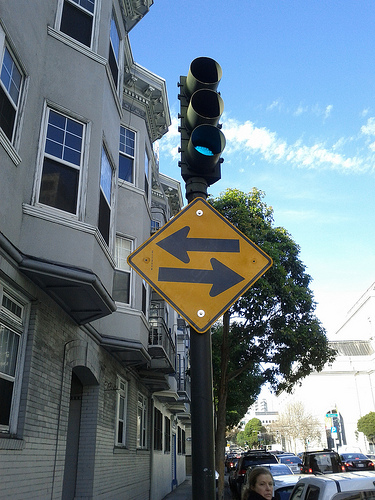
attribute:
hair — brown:
[242, 469, 272, 500]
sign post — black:
[177, 55, 224, 499]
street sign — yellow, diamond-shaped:
[126, 196, 272, 335]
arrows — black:
[156, 224, 245, 298]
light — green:
[186, 125, 226, 170]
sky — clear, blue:
[132, 0, 370, 337]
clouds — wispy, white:
[153, 98, 374, 169]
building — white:
[0, 0, 191, 498]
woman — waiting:
[237, 466, 275, 500]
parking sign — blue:
[329, 423, 339, 432]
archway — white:
[52, 341, 103, 499]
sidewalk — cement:
[158, 471, 229, 499]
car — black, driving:
[338, 453, 374, 472]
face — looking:
[255, 472, 274, 499]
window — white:
[33, 96, 88, 222]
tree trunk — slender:
[211, 305, 236, 499]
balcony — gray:
[148, 311, 177, 378]